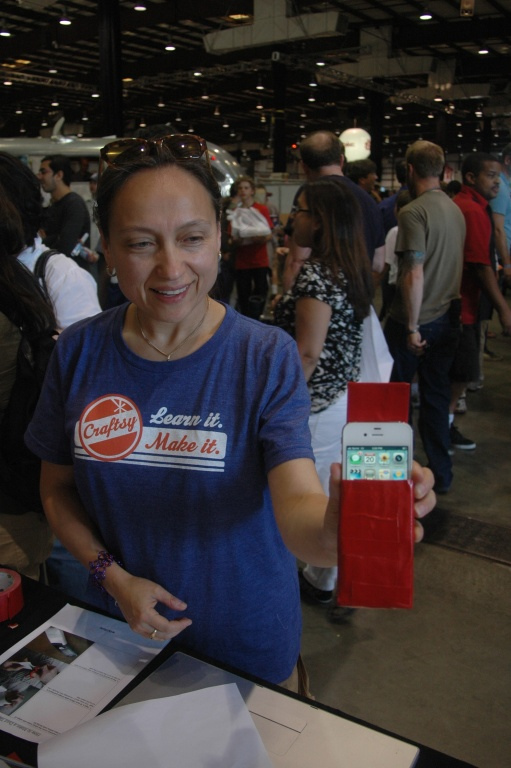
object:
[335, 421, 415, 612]
show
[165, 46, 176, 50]
light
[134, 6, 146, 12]
light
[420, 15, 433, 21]
light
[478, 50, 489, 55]
light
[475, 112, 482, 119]
light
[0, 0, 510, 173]
ceiling